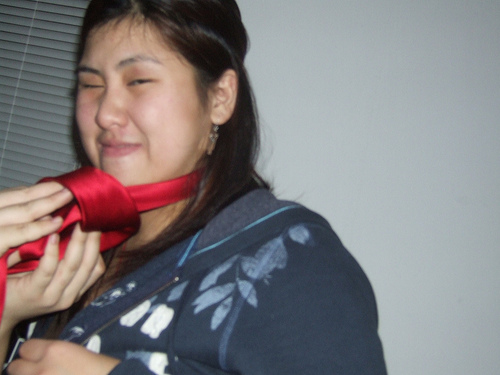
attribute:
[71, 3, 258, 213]
hair — long, black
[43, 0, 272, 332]
hair — up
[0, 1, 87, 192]
blind — mini, white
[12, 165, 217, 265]
tie — red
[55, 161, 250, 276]
tie — red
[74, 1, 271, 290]
hair — dark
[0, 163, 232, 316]
tie — red, silky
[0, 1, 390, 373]
asian woman — Asian 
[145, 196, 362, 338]
jacket — blue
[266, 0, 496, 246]
wall — blank, white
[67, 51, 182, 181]
face — woman's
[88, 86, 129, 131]
nose — big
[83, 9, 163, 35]
bangs — wispy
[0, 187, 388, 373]
blue jacket — blue 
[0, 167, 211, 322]
tie — red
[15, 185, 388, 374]
jacket — blue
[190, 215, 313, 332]
print — floral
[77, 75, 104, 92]
eye — closed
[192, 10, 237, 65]
hair — black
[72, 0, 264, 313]
hair — long, black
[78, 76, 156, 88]
eyes — half closed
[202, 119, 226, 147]
earrings — silver 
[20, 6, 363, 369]
woman — Asian 